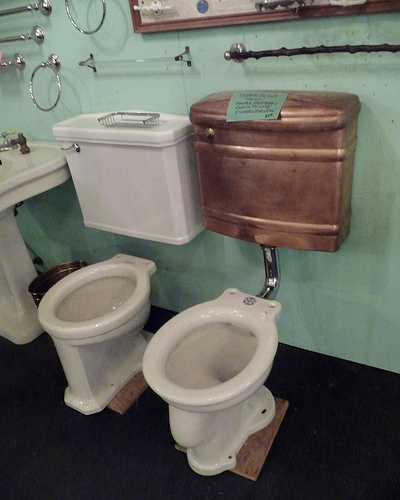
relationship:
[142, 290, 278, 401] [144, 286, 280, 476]
lid on toilet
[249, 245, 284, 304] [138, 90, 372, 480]
frame on toilet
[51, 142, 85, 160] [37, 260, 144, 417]
handle on tank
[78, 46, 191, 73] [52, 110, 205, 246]
bar above tank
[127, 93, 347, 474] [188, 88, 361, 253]
toilet below tank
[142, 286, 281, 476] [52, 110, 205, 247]
shadow below tank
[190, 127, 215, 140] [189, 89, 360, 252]
handle on tank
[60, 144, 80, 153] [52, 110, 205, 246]
handle on tank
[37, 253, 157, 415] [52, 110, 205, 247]
tank below tank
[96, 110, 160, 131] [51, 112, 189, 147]
tray on lid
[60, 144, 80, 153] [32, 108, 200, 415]
handle on toilet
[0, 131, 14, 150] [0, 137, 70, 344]
faucet for sink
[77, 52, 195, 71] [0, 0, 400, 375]
bar on wall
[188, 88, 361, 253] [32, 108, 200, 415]
tank of toilet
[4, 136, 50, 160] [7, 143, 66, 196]
handle of sink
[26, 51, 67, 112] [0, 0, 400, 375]
ring on wall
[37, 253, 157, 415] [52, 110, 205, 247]
tank under tank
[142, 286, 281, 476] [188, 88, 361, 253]
shadow under tank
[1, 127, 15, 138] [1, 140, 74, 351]
knob on sink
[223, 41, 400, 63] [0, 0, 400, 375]
rack on wall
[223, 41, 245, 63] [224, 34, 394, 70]
handle on towel holder